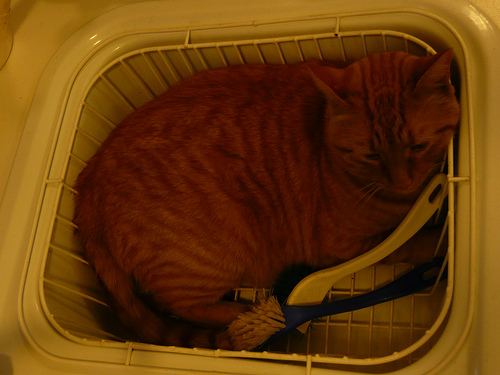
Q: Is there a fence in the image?
A: No, there are no fences.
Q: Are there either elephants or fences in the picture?
A: No, there are no fences or elephants.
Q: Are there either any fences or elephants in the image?
A: No, there are no fences or elephants.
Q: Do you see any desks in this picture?
A: No, there are no desks.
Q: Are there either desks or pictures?
A: No, there are no desks or pictures.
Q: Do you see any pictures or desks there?
A: No, there are no desks or pictures.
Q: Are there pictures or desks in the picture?
A: No, there are no desks or pictures.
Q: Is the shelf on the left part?
A: Yes, the shelf is on the left of the image.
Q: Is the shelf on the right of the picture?
A: No, the shelf is on the left of the image.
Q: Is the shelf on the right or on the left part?
A: The shelf is on the left of the image.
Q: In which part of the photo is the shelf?
A: The shelf is on the left of the image.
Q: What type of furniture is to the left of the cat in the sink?
A: The piece of furniture is a shelf.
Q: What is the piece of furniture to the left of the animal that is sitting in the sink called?
A: The piece of furniture is a shelf.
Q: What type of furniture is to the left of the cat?
A: The piece of furniture is a shelf.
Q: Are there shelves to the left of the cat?
A: Yes, there is a shelf to the left of the cat.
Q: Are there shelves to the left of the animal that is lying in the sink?
A: Yes, there is a shelf to the left of the cat.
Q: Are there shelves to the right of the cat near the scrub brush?
A: No, the shelf is to the left of the cat.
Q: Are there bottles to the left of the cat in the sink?
A: No, there is a shelf to the left of the cat.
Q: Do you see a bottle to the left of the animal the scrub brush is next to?
A: No, there is a shelf to the left of the cat.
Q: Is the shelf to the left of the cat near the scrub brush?
A: Yes, the shelf is to the left of the cat.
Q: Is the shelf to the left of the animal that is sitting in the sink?
A: Yes, the shelf is to the left of the cat.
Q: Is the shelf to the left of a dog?
A: No, the shelf is to the left of the cat.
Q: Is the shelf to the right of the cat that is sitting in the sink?
A: No, the shelf is to the left of the cat.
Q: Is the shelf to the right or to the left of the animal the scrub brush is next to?
A: The shelf is to the left of the cat.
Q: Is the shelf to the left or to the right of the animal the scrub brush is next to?
A: The shelf is to the left of the cat.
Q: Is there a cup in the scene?
A: No, there are no cups.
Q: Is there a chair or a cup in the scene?
A: No, there are no cups or chairs.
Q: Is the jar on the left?
A: Yes, the jar is on the left of the image.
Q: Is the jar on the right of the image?
A: No, the jar is on the left of the image.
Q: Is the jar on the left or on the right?
A: The jar is on the left of the image.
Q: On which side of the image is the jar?
A: The jar is on the left of the image.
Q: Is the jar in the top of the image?
A: Yes, the jar is in the top of the image.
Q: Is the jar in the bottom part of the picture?
A: No, the jar is in the top of the image.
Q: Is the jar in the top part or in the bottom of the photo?
A: The jar is in the top of the image.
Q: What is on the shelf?
A: The jar is on the shelf.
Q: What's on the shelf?
A: The jar is on the shelf.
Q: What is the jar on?
A: The jar is on the shelf.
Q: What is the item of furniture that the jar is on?
A: The piece of furniture is a shelf.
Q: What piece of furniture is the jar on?
A: The jar is on the shelf.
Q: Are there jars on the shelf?
A: Yes, there is a jar on the shelf.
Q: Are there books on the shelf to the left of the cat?
A: No, there is a jar on the shelf.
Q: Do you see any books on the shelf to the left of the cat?
A: No, there is a jar on the shelf.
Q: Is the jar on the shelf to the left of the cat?
A: Yes, the jar is on the shelf.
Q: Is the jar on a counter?
A: No, the jar is on the shelf.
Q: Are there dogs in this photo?
A: No, there are no dogs.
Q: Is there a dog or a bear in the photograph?
A: No, there are no dogs or bears.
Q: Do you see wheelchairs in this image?
A: No, there are no wheelchairs.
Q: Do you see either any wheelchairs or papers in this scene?
A: No, there are no wheelchairs or papers.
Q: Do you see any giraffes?
A: No, there are no giraffes.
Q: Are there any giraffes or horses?
A: No, there are no giraffes or horses.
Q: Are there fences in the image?
A: No, there are no fences.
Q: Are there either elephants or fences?
A: No, there are no fences or elephants.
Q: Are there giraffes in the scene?
A: No, there are no giraffes.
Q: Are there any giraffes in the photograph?
A: No, there are no giraffes.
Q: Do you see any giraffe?
A: No, there are no giraffes.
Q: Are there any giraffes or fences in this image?
A: No, there are no giraffes or fences.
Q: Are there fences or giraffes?
A: No, there are no giraffes or fences.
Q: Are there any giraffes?
A: No, there are no giraffes.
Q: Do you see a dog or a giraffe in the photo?
A: No, there are no giraffes or dogs.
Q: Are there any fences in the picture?
A: No, there are no fences.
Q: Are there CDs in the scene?
A: No, there are no cds.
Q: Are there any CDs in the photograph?
A: No, there are no cds.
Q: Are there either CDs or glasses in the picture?
A: No, there are no CDs or glasses.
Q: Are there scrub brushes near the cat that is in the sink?
A: Yes, there is a scrub brush near the cat.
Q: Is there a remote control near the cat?
A: No, there is a scrub brush near the cat.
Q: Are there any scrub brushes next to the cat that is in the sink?
A: Yes, there is a scrub brush next to the cat.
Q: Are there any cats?
A: Yes, there is a cat.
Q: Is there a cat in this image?
A: Yes, there is a cat.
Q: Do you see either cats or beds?
A: Yes, there is a cat.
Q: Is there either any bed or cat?
A: Yes, there is a cat.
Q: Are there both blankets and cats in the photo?
A: No, there is a cat but no blankets.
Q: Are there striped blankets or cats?
A: Yes, there is a striped cat.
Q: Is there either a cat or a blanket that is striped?
A: Yes, the cat is striped.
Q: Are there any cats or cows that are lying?
A: Yes, the cat is lying.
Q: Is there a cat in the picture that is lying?
A: Yes, there is a cat that is lying.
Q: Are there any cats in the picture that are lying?
A: Yes, there is a cat that is lying.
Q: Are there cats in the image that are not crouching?
A: Yes, there is a cat that is lying.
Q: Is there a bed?
A: No, there are no beds.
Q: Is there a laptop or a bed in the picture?
A: No, there are no beds or laptops.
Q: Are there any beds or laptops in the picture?
A: No, there are no beds or laptops.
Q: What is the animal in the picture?
A: The animal is a cat.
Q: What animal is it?
A: The animal is a cat.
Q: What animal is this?
A: This is a cat.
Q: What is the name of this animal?
A: This is a cat.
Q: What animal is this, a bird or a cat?
A: This is a cat.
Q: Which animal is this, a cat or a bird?
A: This is a cat.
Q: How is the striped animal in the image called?
A: The animal is a cat.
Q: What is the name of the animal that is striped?
A: The animal is a cat.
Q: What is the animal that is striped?
A: The animal is a cat.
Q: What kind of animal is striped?
A: The animal is a cat.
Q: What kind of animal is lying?
A: The animal is a cat.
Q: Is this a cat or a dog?
A: This is a cat.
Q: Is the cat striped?
A: Yes, the cat is striped.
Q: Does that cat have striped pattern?
A: Yes, the cat is striped.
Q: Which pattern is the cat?
A: The cat is striped.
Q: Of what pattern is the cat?
A: The cat is striped.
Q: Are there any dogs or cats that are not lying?
A: No, there is a cat but it is lying.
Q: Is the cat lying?
A: Yes, the cat is lying.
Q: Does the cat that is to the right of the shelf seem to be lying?
A: Yes, the cat is lying.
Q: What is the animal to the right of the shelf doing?
A: The cat is lying.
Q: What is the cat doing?
A: The cat is lying.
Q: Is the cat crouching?
A: No, the cat is lying.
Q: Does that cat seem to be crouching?
A: No, the cat is lying.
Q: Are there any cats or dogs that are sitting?
A: No, there is a cat but it is lying.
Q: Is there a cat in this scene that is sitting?
A: No, there is a cat but it is lying.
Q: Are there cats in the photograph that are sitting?
A: No, there is a cat but it is lying.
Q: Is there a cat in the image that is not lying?
A: No, there is a cat but it is lying.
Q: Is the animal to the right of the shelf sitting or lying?
A: The cat is lying.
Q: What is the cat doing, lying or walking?
A: The cat is lying.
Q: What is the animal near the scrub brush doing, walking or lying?
A: The cat is lying.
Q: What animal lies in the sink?
A: The cat lies in the sink.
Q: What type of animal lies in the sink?
A: The animal is a cat.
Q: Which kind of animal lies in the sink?
A: The animal is a cat.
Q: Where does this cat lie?
A: The cat lies in the sink.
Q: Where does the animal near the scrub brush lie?
A: The cat lies in the sink.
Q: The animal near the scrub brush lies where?
A: The cat lies in the sink.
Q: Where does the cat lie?
A: The cat lies in the sink.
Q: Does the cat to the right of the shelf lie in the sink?
A: Yes, the cat lies in the sink.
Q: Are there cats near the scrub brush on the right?
A: Yes, there is a cat near the scrub brush.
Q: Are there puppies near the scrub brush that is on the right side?
A: No, there is a cat near the scrub brush.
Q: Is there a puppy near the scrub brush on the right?
A: No, there is a cat near the scrub brush.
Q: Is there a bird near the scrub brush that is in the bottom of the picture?
A: No, there is a cat near the scrub brush.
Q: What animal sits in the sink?
A: The cat sits in the sink.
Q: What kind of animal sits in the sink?
A: The animal is a cat.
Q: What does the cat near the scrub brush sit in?
A: The cat sits in the sink.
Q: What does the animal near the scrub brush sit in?
A: The cat sits in the sink.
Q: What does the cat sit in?
A: The cat sits in the sink.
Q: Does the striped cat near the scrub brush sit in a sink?
A: Yes, the cat sits in a sink.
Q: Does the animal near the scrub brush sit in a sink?
A: Yes, the cat sits in a sink.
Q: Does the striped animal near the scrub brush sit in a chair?
A: No, the cat sits in a sink.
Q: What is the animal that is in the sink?
A: The animal is a cat.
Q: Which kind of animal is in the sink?
A: The animal is a cat.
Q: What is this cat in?
A: The cat is in the sink.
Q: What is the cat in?
A: The cat is in the sink.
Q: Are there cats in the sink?
A: Yes, there is a cat in the sink.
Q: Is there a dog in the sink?
A: No, there is a cat in the sink.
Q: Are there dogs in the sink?
A: No, there is a cat in the sink.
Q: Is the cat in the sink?
A: Yes, the cat is in the sink.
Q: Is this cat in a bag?
A: No, the cat is in the sink.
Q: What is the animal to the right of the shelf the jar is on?
A: The animal is a cat.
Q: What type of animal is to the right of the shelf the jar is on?
A: The animal is a cat.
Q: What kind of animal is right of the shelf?
A: The animal is a cat.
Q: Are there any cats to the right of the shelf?
A: Yes, there is a cat to the right of the shelf.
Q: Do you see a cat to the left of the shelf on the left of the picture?
A: No, the cat is to the right of the shelf.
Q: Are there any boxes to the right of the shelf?
A: No, there is a cat to the right of the shelf.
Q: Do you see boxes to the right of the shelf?
A: No, there is a cat to the right of the shelf.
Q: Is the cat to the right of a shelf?
A: Yes, the cat is to the right of a shelf.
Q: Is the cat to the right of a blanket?
A: No, the cat is to the right of a shelf.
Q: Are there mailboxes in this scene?
A: No, there are no mailboxes.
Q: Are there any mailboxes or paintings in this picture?
A: No, there are no mailboxes or paintings.